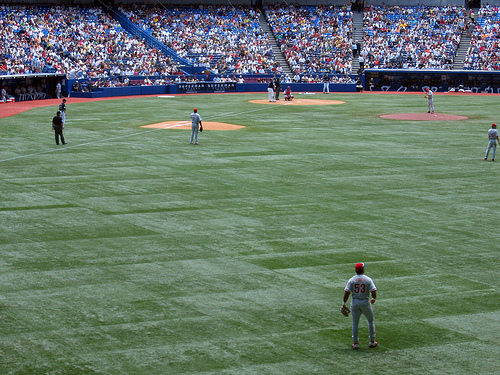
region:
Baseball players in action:
[24, 52, 499, 344]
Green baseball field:
[61, 157, 426, 254]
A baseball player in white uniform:
[319, 237, 416, 359]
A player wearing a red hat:
[338, 239, 380, 291]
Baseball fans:
[55, 11, 282, 90]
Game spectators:
[11, 5, 498, 97]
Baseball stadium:
[5, 2, 482, 235]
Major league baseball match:
[13, 7, 498, 302]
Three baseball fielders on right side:
[177, 101, 497, 358]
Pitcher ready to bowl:
[401, 68, 476, 143]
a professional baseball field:
[3, 47, 498, 367]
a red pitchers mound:
[378, 86, 482, 132]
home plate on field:
[252, 86, 353, 120]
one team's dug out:
[3, 62, 73, 112]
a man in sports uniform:
[328, 252, 399, 356]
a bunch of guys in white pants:
[372, 71, 489, 102]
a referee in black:
[41, 106, 73, 165]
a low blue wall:
[86, 64, 371, 104]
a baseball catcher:
[279, 81, 301, 104]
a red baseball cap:
[343, 245, 373, 274]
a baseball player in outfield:
[257, 207, 427, 361]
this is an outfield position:
[287, 211, 477, 369]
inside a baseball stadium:
[18, 17, 472, 361]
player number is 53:
[316, 249, 448, 353]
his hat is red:
[273, 196, 413, 357]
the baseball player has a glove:
[324, 222, 428, 358]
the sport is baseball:
[34, 60, 469, 310]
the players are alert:
[31, 45, 478, 316]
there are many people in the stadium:
[20, 25, 461, 86]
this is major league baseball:
[21, 25, 483, 339]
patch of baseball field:
[48, 196, 255, 349]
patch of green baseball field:
[59, 195, 272, 345]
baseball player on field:
[316, 250, 397, 350]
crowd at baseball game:
[2, 11, 497, 94]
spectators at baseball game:
[5, 13, 494, 75]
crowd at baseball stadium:
[12, 11, 494, 83]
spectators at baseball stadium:
[7, 8, 486, 84]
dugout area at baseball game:
[0, 66, 72, 107]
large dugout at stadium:
[342, 63, 497, 101]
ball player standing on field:
[177, 103, 221, 159]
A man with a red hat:
[336, 247, 381, 286]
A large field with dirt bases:
[7, 95, 492, 367]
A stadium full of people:
[13, 10, 460, 110]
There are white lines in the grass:
[0, 93, 350, 179]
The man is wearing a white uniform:
[329, 258, 392, 350]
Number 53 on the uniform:
[350, 280, 371, 299]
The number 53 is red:
[350, 277, 371, 302]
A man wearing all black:
[47, 111, 74, 155]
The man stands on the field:
[332, 248, 398, 357]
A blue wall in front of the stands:
[87, 74, 347, 104]